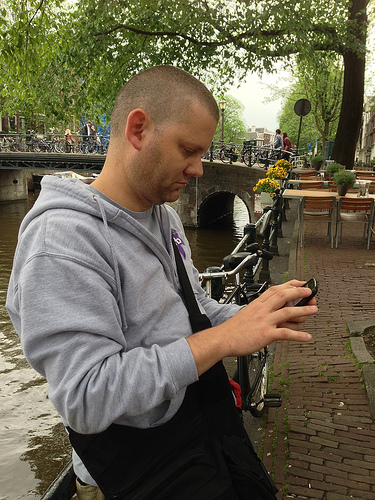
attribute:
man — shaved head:
[5, 62, 319, 496]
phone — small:
[281, 278, 317, 311]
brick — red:
[287, 484, 321, 497]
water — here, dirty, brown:
[183, 195, 249, 273]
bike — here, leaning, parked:
[193, 250, 271, 306]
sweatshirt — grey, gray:
[4, 173, 248, 435]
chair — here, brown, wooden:
[292, 193, 339, 257]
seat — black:
[222, 250, 256, 268]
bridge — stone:
[165, 138, 292, 228]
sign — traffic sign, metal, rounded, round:
[294, 99, 310, 116]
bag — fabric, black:
[67, 361, 285, 499]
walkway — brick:
[220, 210, 373, 498]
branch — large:
[57, 0, 343, 123]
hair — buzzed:
[107, 64, 218, 141]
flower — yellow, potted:
[252, 177, 281, 209]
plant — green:
[332, 169, 356, 196]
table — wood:
[280, 190, 373, 245]